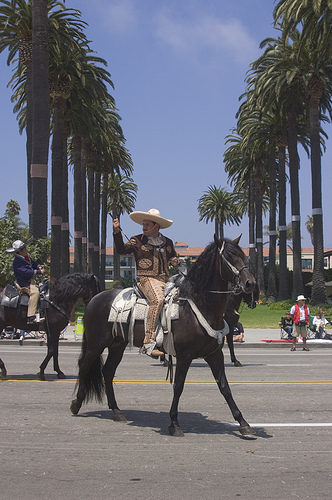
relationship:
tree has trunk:
[286, 25, 304, 304] [287, 141, 303, 293]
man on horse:
[112, 207, 179, 360] [68, 232, 260, 445]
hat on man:
[128, 208, 172, 229] [112, 207, 179, 360]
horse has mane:
[68, 232, 260, 445] [185, 233, 227, 289]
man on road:
[290, 293, 311, 351] [243, 342, 332, 397]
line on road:
[231, 419, 329, 427] [1, 347, 330, 495]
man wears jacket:
[6, 234, 49, 325] [6, 253, 42, 288]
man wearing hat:
[5, 237, 49, 325] [4, 235, 34, 255]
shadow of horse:
[69, 409, 272, 440] [68, 232, 260, 445]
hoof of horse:
[238, 426, 257, 437] [68, 232, 260, 445]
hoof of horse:
[167, 424, 185, 437] [68, 232, 260, 445]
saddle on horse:
[108, 287, 181, 323] [68, 232, 260, 445]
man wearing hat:
[112, 207, 177, 356] [128, 208, 172, 229]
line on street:
[231, 419, 329, 427] [3, 346, 331, 499]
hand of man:
[111, 215, 119, 229] [108, 204, 175, 357]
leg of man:
[139, 278, 165, 357] [112, 207, 177, 356]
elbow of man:
[115, 243, 127, 255] [112, 207, 177, 356]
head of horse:
[199, 233, 258, 309] [68, 232, 260, 445]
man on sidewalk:
[290, 293, 311, 351] [47, 323, 321, 345]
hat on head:
[128, 208, 172, 229] [139, 219, 163, 243]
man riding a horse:
[112, 207, 179, 360] [68, 232, 260, 445]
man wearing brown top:
[112, 207, 179, 360] [142, 236, 173, 281]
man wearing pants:
[112, 207, 179, 360] [133, 276, 183, 362]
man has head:
[112, 207, 179, 360] [141, 216, 158, 238]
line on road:
[6, 373, 331, 387] [1, 337, 332, 496]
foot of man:
[145, 344, 165, 356] [111, 196, 189, 357]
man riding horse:
[112, 207, 179, 360] [68, 232, 260, 445]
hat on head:
[131, 207, 172, 230] [141, 218, 162, 237]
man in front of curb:
[290, 293, 311, 351] [1, 333, 321, 349]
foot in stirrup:
[145, 344, 165, 356] [145, 336, 158, 357]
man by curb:
[288, 293, 312, 350] [2, 336, 321, 349]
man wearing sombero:
[112, 207, 179, 360] [128, 207, 172, 229]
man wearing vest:
[290, 293, 311, 351] [292, 301, 310, 325]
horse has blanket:
[68, 232, 260, 445] [110, 281, 183, 325]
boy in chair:
[280, 310, 294, 337] [278, 315, 294, 340]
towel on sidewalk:
[262, 338, 297, 344] [9, 316, 320, 344]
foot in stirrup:
[141, 344, 165, 359] [140, 339, 161, 356]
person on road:
[225, 313, 244, 346] [1, 337, 332, 496]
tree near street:
[252, 36, 279, 300] [3, 346, 331, 499]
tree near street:
[244, 37, 308, 301] [0, 337, 321, 495]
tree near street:
[229, 128, 257, 278] [0, 337, 321, 495]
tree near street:
[92, 121, 132, 285] [0, 337, 321, 495]